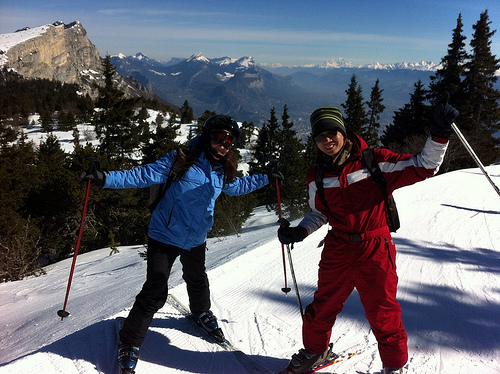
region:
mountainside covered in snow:
[163, 46, 275, 89]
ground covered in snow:
[90, 286, 119, 311]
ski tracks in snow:
[225, 296, 282, 338]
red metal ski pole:
[49, 188, 102, 328]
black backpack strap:
[166, 147, 181, 182]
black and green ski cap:
[298, 103, 354, 130]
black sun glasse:
[308, 126, 340, 143]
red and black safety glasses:
[206, 126, 238, 148]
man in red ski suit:
[275, 105, 498, 369]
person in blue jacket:
[83, 101, 264, 256]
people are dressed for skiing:
[108, 102, 382, 344]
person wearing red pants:
[311, 221, 401, 317]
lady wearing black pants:
[156, 214, 236, 349]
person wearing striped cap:
[309, 105, 365, 147]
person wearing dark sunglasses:
[305, 129, 345, 137]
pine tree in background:
[349, 72, 369, 152]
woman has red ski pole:
[75, 130, 99, 335]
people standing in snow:
[122, 90, 371, 355]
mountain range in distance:
[208, 66, 320, 112]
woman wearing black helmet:
[195, 107, 237, 177]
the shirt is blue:
[122, 158, 276, 258]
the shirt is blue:
[93, 158, 305, 349]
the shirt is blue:
[117, 182, 205, 270]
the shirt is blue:
[145, 152, 213, 219]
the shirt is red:
[287, 187, 411, 335]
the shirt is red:
[259, 205, 466, 353]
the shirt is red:
[290, 181, 435, 262]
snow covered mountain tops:
[170, 44, 272, 88]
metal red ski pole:
[59, 194, 98, 324]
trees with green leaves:
[4, 144, 75, 209]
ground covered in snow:
[223, 267, 263, 294]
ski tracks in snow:
[415, 239, 498, 319]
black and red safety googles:
[209, 129, 241, 151]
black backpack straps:
[149, 148, 181, 225]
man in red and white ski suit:
[270, 88, 442, 371]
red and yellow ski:
[307, 344, 368, 372]